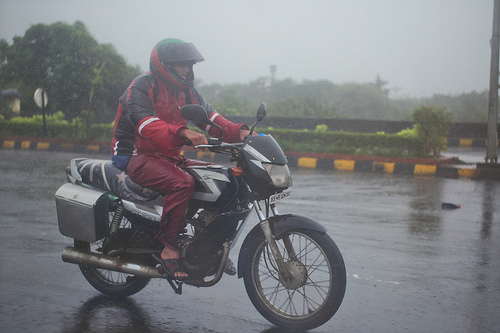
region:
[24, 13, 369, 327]
Motorcycle on the wet road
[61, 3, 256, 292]
Man riding a motorcycle.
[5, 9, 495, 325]
Weather is rainy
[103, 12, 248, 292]
Man wearing red.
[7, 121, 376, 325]
Motorcycle is silver and black.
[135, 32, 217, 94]
Helmet on man's head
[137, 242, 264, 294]
Man wearing sandals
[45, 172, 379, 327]
Two wheels on the motorcycle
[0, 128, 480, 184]
Black and yellow curb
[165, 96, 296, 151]
Two side view mirrors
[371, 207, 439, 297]
this is the road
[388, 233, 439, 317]
the road is wet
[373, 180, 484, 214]
rainwater on the road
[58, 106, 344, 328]
this is a motorcycle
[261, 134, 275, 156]
the motorcycle is black in color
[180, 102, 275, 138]
these are two side mirrors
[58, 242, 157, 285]
this is an exhaust pipe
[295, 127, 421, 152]
this is a hedge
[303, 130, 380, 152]
the hedge has some leaves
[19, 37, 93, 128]
the tree has green leaves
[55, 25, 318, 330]
A person on a motorcycle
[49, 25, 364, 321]
A person on a motorcycle in the rain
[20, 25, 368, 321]
A wet person on a motorcycle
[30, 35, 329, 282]
a person in a red suit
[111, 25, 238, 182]
a person wearing a helmet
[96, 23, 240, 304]
a person wearing sandals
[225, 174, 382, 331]
The front wheel of a motorcycle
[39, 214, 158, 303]
The rear wheel of a motorcycle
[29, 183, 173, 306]
The muffler of a motorcycle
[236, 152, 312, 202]
The headlight of a motorcycle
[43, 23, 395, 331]
The man is on a motorcycle.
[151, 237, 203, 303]
The man wears sandals.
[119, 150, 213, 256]
The man wears red pants.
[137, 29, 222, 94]
The man wears a helmet.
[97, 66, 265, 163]
The man wears a red jacket.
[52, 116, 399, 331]
The motorcycle is black and white.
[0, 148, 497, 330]
The road is wet.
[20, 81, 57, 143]
A sign is in the background.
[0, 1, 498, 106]
The sky is overcast.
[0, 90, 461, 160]
Hedges lines the road.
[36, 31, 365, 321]
man riding on motorbike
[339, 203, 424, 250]
wet asphalt on street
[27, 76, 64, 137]
back of sign on curb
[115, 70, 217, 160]
red and black jacket on man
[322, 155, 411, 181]
black and yellow curb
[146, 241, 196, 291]
man's foot in sandle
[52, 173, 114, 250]
storage on back of bike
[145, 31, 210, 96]
helmet with visor up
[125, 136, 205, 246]
wet red pants on man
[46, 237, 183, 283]
exhaust pipe on motorcycle